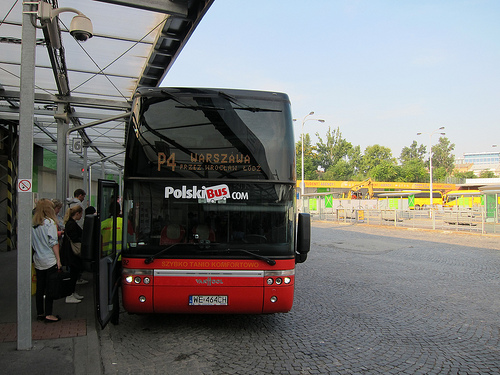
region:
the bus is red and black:
[123, 90, 291, 307]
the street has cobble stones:
[98, 218, 497, 372]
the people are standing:
[31, 189, 127, 320]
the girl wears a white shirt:
[38, 222, 60, 274]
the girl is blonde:
[30, 200, 54, 224]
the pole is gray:
[18, 8, 35, 349]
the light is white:
[30, 1, 94, 32]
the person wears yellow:
[96, 213, 126, 254]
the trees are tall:
[294, 127, 459, 179]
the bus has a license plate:
[185, 293, 230, 306]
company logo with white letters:
[162, 181, 256, 204]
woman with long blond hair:
[31, 198, 77, 325]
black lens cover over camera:
[72, 32, 92, 42]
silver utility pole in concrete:
[16, 2, 38, 353]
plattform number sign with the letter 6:
[72, 137, 84, 154]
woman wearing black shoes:
[41, 316, 65, 324]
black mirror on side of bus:
[295, 214, 313, 267]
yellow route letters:
[155, 148, 273, 178]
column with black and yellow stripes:
[1, 150, 18, 252]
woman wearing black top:
[61, 198, 88, 306]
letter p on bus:
[151, 148, 168, 175]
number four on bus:
[164, 148, 179, 174]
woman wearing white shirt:
[41, 236, 43, 244]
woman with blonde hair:
[40, 206, 45, 212]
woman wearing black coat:
[71, 226, 79, 238]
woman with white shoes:
[63, 291, 87, 308]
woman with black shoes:
[31, 309, 66, 324]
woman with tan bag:
[72, 243, 82, 254]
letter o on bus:
[171, 185, 181, 200]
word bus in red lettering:
[206, 183, 231, 201]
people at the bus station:
[26, 176, 115, 318]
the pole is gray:
[8, 53, 45, 363]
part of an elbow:
[116, 338, 124, 344]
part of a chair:
[389, 178, 414, 223]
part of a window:
[309, 197, 320, 222]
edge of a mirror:
[291, 236, 298, 238]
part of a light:
[167, 302, 174, 327]